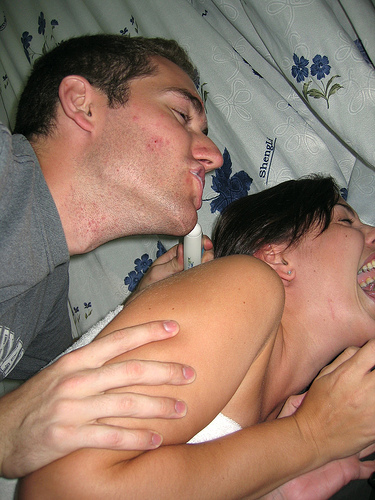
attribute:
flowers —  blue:
[290, 52, 330, 81]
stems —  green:
[307, 79, 325, 94]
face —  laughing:
[298, 182, 373, 339]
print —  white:
[1, 323, 25, 380]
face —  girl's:
[304, 184, 374, 337]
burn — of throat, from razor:
[70, 193, 117, 236]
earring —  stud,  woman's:
[287, 269, 291, 275]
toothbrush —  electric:
[184, 221, 200, 272]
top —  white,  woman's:
[182, 412, 246, 444]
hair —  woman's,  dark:
[208, 171, 340, 257]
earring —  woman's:
[285, 268, 291, 273]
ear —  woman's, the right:
[249, 242, 300, 280]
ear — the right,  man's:
[58, 73, 93, 134]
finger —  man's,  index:
[73, 317, 179, 356]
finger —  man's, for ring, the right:
[86, 392, 188, 419]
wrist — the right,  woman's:
[289, 411, 329, 476]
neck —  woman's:
[281, 300, 319, 392]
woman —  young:
[6, 174, 374, 498]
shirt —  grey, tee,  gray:
[2, 124, 70, 383]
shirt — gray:
[1, 122, 78, 383]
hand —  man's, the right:
[1, 308, 203, 487]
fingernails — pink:
[153, 317, 195, 456]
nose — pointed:
[188, 126, 227, 173]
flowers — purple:
[286, 47, 335, 83]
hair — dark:
[205, 169, 348, 265]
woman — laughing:
[206, 167, 373, 420]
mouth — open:
[354, 251, 374, 300]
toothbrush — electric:
[179, 217, 206, 268]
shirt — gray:
[1, 120, 85, 391]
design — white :
[272, 91, 310, 147]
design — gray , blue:
[290, 51, 332, 109]